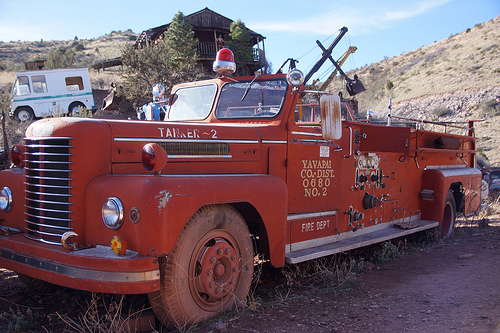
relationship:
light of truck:
[0, 185, 12, 210] [9, 69, 487, 331]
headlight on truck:
[49, 187, 160, 272] [49, 58, 494, 324]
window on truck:
[213, 79, 288, 120] [9, 69, 487, 331]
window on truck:
[213, 79, 288, 120] [4, 47, 494, 326]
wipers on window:
[237, 67, 265, 109] [220, 75, 289, 130]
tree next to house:
[114, 9, 207, 114] [139, 3, 277, 86]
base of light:
[210, 61, 239, 75] [214, 44, 236, 58]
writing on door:
[295, 157, 336, 199] [284, 86, 347, 217]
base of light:
[212, 48, 234, 75] [209, 42, 239, 79]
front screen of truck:
[177, 90, 272, 117] [112, 84, 455, 228]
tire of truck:
[149, 206, 262, 323] [5, 55, 499, 295]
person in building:
[205, 25, 235, 52] [24, 7, 265, 77]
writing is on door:
[299, 160, 332, 196] [285, 124, 341, 251]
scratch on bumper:
[151, 190, 175, 211] [4, 229, 159, 299]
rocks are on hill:
[357, 27, 480, 245] [86, 15, 496, 197]